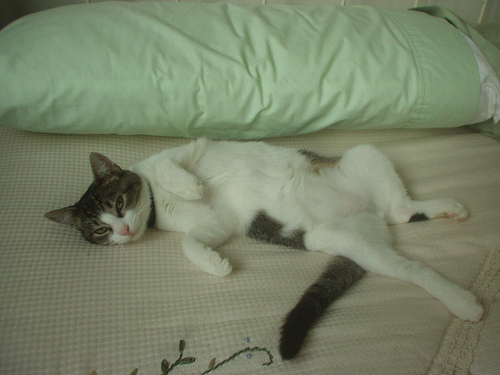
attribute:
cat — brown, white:
[62, 157, 422, 315]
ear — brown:
[83, 157, 117, 178]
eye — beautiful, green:
[111, 187, 137, 231]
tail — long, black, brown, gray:
[266, 272, 344, 330]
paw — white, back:
[160, 171, 200, 203]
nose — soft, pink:
[113, 221, 143, 235]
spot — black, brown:
[245, 208, 305, 250]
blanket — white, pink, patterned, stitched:
[64, 300, 135, 335]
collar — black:
[138, 166, 173, 255]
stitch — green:
[153, 356, 239, 372]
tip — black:
[282, 331, 302, 356]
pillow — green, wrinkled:
[81, 35, 146, 92]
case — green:
[440, 47, 467, 88]